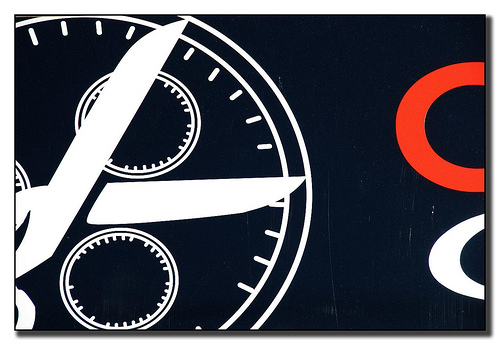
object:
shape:
[11, 3, 312, 330]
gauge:
[12, 16, 323, 330]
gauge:
[52, 227, 179, 331]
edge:
[95, 176, 305, 196]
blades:
[50, 20, 192, 214]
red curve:
[385, 54, 485, 195]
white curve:
[426, 211, 483, 306]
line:
[323, 177, 342, 335]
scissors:
[13, 18, 306, 329]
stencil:
[22, 17, 330, 329]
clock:
[20, 18, 317, 333]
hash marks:
[89, 75, 192, 170]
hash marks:
[14, 17, 290, 329]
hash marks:
[64, 230, 171, 327]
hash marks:
[13, 167, 23, 191]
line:
[425, 211, 486, 309]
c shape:
[393, 57, 484, 192]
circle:
[57, 226, 179, 344]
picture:
[14, 14, 488, 327]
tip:
[269, 175, 308, 201]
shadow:
[81, 179, 106, 226]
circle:
[12, 22, 324, 333]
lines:
[193, 101, 203, 126]